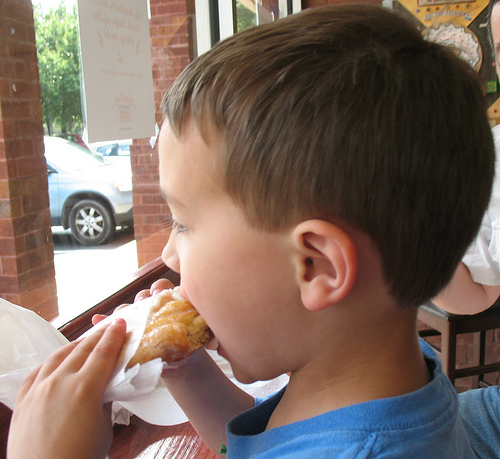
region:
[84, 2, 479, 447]
this is a boy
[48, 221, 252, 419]
the boy is eating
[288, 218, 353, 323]
this is an ear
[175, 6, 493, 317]
the boy has brown hair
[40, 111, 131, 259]
this is a car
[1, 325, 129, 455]
the hand of a boy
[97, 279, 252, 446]
the hand of a boy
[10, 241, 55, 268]
Small red bricks making a beam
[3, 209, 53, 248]
Small red bricks making a beam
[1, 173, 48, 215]
Small red bricks making a beam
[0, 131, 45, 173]
Small red bricks making a beam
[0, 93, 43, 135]
Small red bricks making a beam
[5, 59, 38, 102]
Small red bricks making a beam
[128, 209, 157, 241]
Small red bricks making a beam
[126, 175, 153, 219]
Small red bricks making a beam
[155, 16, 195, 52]
Small red bricks making a beam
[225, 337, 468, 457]
blue t-shirt on a little boy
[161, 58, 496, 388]
little boy with short brown hair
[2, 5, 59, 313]
brick pillar holds up roof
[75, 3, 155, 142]
sign hangs in the entryway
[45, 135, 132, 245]
car parked in the parking lot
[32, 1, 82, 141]
tree past the parking lot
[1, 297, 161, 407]
white waxed paper holds food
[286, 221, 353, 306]
a left ear of a little boy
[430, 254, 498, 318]
an adult's elbow with a white shirt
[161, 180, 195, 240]
an eyebrow and an eye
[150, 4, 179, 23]
Red brick on a column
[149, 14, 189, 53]
Red brick on a column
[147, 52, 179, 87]
Red brick on a column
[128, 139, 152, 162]
Red brick on a column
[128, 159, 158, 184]
Red brick on a column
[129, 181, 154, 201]
Red brick on a column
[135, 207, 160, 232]
Red brick on a column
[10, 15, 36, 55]
Red brick on a column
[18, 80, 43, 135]
Red brick on a column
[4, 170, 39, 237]
Red brick on a column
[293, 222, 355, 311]
The ear of the boy.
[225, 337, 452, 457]
The blue shirt the kid is wearing.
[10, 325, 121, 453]
The kid's right hand.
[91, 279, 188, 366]
The kid's left hand.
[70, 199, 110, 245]
The front tire of the car.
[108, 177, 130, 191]
The headlight on the vehicle.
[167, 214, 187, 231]
The eye of the kid.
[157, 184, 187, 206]
The eyebrow of the kid.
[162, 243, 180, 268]
The nose of the kid.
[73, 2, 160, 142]
The paper taped to the window of the establishment.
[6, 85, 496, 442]
a scene during the day time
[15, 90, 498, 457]
a scene inside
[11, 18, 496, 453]
a scene of a restaurant